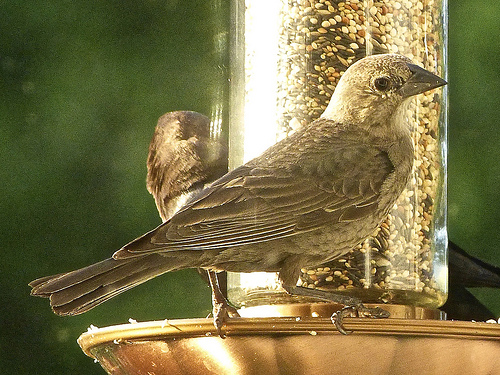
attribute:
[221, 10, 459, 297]
bird seed — a lot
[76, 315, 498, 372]
feeder base — copper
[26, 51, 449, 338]
bird — brown, little, small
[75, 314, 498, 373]
dish — gold, metallic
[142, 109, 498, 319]
bird — small, brown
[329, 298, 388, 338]
bird foot — brown, tiny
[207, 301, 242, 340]
bird foot — brown, tiny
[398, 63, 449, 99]
beak — small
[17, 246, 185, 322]
tail feather — brown, long